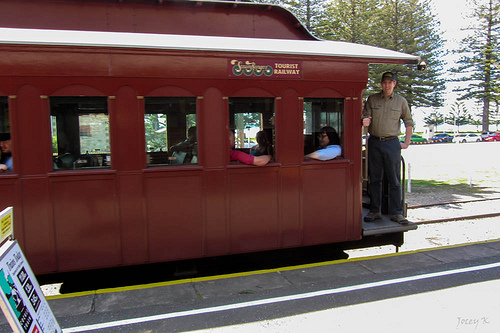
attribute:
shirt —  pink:
[215, 149, 256, 161]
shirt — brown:
[358, 80, 422, 137]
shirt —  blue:
[316, 142, 341, 161]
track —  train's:
[398, 189, 499, 226]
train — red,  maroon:
[0, 0, 428, 289]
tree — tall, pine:
[447, 0, 499, 131]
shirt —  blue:
[315, 145, 338, 157]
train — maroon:
[3, 6, 431, 267]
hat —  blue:
[374, 67, 410, 83]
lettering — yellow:
[384, 70, 394, 77]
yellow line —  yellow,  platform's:
[132, 278, 202, 294]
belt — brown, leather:
[367, 132, 397, 140]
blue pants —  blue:
[365, 132, 406, 222]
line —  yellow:
[28, 200, 498, 256]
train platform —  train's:
[72, 264, 474, 331]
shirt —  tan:
[363, 90, 412, 139]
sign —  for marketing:
[0, 239, 65, 331]